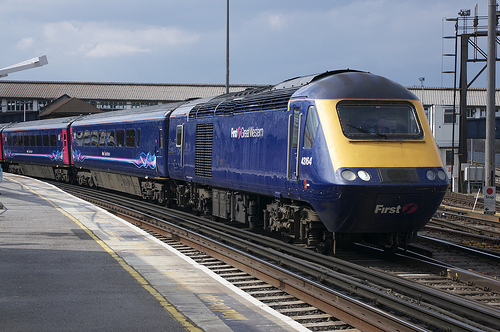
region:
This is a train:
[63, 70, 428, 245]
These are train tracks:
[149, 192, 378, 329]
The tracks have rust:
[213, 241, 298, 311]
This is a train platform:
[16, 246, 173, 321]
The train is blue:
[229, 66, 477, 237]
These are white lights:
[338, 153, 498, 198]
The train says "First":
[349, 187, 429, 239]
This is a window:
[333, 90, 466, 154]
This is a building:
[29, 68, 147, 98]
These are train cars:
[35, 92, 207, 168]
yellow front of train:
[318, 95, 438, 177]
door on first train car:
[279, 101, 306, 184]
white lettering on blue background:
[369, 198, 404, 224]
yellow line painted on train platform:
[18, 177, 173, 330]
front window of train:
[338, 101, 416, 139]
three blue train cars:
[6, 62, 204, 237]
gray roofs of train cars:
[1, 105, 195, 135]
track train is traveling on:
[76, 134, 478, 330]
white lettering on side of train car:
[216, 115, 271, 144]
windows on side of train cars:
[7, 119, 190, 146]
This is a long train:
[71, 5, 498, 264]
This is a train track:
[203, 248, 339, 321]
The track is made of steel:
[242, 215, 435, 330]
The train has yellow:
[219, 98, 424, 185]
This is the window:
[337, 60, 491, 187]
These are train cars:
[44, 130, 180, 211]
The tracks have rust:
[288, 254, 420, 306]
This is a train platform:
[23, 170, 119, 322]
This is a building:
[42, 86, 94, 131]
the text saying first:
[367, 197, 401, 221]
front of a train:
[297, 61, 452, 253]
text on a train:
[223, 123, 275, 140]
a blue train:
[4, 65, 439, 246]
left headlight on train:
[335, 166, 373, 178]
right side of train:
[420, 167, 453, 182]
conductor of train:
[361, 116, 398, 134]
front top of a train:
[302, 62, 417, 97]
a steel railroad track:
[138, 196, 310, 287]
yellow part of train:
[318, 93, 452, 165]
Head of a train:
[165, 53, 466, 264]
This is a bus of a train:
[61, 57, 187, 222]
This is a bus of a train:
[1, 110, 86, 198]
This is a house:
[0, 58, 267, 118]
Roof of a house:
[3, 69, 267, 103]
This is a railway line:
[127, 191, 343, 311]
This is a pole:
[447, 3, 477, 233]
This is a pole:
[476, 0, 498, 208]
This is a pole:
[215, 0, 247, 105]